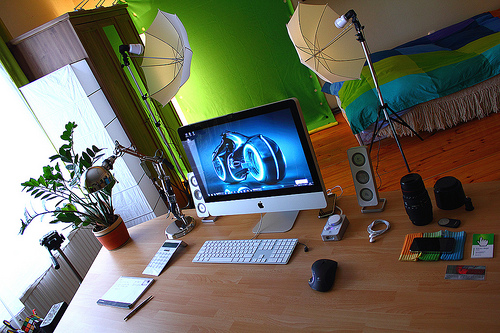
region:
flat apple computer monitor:
[175, 111, 325, 219]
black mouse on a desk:
[306, 255, 340, 293]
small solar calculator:
[140, 237, 187, 279]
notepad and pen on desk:
[92, 272, 159, 319]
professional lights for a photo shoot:
[106, 11, 194, 162]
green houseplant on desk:
[13, 120, 145, 252]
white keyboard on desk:
[196, 234, 302, 279]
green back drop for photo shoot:
[196, 21, 271, 88]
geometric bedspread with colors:
[385, 47, 452, 87]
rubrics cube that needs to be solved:
[21, 316, 46, 330]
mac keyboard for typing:
[189, 235, 299, 265]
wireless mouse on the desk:
[307, 256, 339, 293]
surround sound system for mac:
[345, 145, 385, 212]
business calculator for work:
[140, 237, 186, 276]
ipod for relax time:
[406, 235, 458, 255]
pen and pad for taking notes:
[94, 274, 159, 321]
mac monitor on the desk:
[175, 95, 330, 220]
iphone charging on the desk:
[316, 190, 337, 222]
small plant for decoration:
[34, 137, 130, 251]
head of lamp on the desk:
[79, 141, 122, 199]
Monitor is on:
[171, 112, 326, 210]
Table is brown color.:
[184, 273, 315, 325]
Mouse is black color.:
[304, 253, 344, 298]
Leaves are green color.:
[40, 162, 102, 232]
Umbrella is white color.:
[130, 16, 365, 77]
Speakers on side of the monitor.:
[163, 148, 384, 222]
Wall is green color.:
[214, 35, 302, 113]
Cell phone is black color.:
[395, 230, 475, 265]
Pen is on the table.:
[125, 293, 163, 320]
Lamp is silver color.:
[78, 150, 189, 242]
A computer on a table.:
[141, 101, 377, 311]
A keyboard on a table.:
[185, 225, 295, 270]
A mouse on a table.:
[305, 237, 350, 302]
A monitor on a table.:
[160, 87, 335, 227]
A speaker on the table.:
[335, 132, 391, 217]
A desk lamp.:
[60, 121, 200, 256]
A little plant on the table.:
[0, 120, 145, 265]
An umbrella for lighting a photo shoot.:
[270, 0, 400, 90]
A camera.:
[15, 210, 80, 275]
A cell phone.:
[388, 226, 464, 267]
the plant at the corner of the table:
[24, 123, 128, 240]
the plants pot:
[91, 217, 129, 247]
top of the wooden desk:
[183, 275, 295, 331]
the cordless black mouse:
[311, 257, 335, 298]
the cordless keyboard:
[196, 238, 293, 260]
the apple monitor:
[177, 110, 324, 224]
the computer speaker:
[348, 144, 385, 211]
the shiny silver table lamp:
[76, 142, 192, 239]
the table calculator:
[142, 237, 187, 274]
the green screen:
[205, 55, 292, 91]